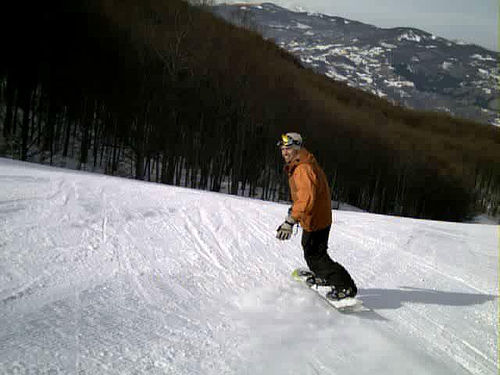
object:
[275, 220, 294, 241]
gloved hand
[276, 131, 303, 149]
cap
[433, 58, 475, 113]
wall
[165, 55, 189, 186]
tree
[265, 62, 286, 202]
tree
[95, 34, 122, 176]
tree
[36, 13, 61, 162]
tree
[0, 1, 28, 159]
tree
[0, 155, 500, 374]
ground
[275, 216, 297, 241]
glove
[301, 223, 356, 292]
black pants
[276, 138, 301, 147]
goggles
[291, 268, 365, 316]
snowboard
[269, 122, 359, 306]
snowboarder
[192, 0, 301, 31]
wall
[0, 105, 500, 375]
snow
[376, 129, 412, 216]
trees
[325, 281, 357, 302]
boot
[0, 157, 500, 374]
tracks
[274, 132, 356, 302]
man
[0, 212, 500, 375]
slope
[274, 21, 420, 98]
snow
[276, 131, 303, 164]
head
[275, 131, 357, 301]
boarder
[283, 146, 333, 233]
jacket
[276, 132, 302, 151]
hat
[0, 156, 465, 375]
patches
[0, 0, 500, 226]
mountain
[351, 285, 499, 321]
shadow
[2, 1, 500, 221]
side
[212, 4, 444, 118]
patches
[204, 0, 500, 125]
mountain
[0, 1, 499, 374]
background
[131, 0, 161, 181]
trees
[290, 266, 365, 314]
board